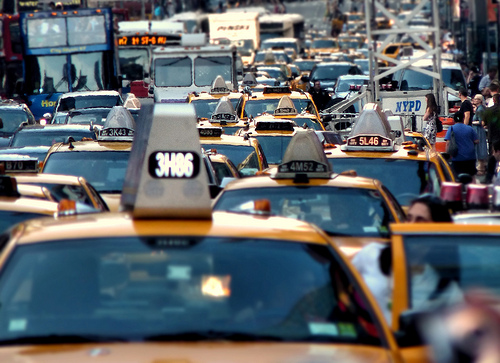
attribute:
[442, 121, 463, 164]
purse — gray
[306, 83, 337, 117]
shirt — black 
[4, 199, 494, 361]
cab — yellow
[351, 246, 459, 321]
shirt — white